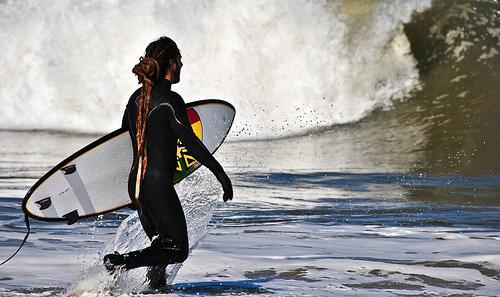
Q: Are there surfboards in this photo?
A: Yes, there is a surfboard.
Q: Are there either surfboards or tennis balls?
A: Yes, there is a surfboard.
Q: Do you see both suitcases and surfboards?
A: No, there is a surfboard but no suitcases.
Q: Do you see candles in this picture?
A: No, there are no candles.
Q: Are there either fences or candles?
A: No, there are no candles or fences.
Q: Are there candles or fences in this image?
A: No, there are no candles or fences.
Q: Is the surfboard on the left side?
A: Yes, the surfboard is on the left of the image.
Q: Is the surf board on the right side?
A: No, the surf board is on the left of the image.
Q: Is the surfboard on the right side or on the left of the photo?
A: The surfboard is on the left of the image.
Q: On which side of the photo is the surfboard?
A: The surfboard is on the left of the image.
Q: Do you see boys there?
A: No, there are no boys.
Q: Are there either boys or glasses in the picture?
A: No, there are no boys or glasses.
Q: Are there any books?
A: No, there are no books.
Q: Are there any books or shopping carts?
A: No, there are no books or shopping carts.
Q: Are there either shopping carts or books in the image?
A: No, there are no books or shopping carts.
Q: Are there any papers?
A: No, there are no papers.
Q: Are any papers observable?
A: No, there are no papers.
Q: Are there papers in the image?
A: No, there are no papers.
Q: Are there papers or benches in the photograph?
A: No, there are no papers or benches.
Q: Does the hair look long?
A: Yes, the hair is long.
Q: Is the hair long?
A: Yes, the hair is long.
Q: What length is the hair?
A: The hair is long.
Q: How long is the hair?
A: The hair is long.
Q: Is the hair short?
A: No, the hair is long.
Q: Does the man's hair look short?
A: No, the hair is long.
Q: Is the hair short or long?
A: The hair is long.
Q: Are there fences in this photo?
A: No, there are no fences.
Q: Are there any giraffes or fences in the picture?
A: No, there are no fences or giraffes.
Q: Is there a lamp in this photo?
A: No, there are no lamps.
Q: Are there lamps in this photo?
A: No, there are no lamps.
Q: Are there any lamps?
A: No, there are no lamps.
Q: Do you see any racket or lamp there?
A: No, there are no lamps or rackets.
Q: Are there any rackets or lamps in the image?
A: No, there are no lamps or rackets.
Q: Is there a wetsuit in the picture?
A: Yes, there is a wetsuit.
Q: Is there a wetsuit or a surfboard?
A: Yes, there is a wetsuit.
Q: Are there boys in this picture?
A: No, there are no boys.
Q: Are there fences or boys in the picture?
A: No, there are no boys or fences.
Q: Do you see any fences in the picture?
A: No, there are no fences.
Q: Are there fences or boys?
A: No, there are no fences or boys.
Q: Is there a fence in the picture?
A: No, there are no fences.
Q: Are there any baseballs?
A: No, there are no baseballs.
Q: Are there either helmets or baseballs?
A: No, there are no baseballs or helmets.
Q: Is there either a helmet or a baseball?
A: No, there are no baseballs or helmets.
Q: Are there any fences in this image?
A: No, there are no fences.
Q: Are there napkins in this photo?
A: No, there are no napkins.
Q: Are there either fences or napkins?
A: No, there are no napkins or fences.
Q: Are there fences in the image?
A: No, there are no fences.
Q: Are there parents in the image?
A: No, there are no parents.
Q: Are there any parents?
A: No, there are no parents.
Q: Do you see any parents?
A: No, there are no parents.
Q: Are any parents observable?
A: No, there are no parents.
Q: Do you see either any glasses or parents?
A: No, there are no parents or glasses.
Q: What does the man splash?
A: The man splashes the water.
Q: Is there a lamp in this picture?
A: No, there are no lamps.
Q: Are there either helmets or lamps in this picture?
A: No, there are no lamps or helmets.